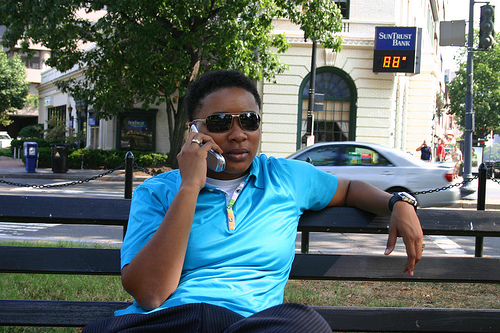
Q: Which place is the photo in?
A: It is at the road.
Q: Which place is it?
A: It is a road.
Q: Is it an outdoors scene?
A: Yes, it is outdoors.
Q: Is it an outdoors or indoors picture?
A: It is outdoors.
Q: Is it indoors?
A: No, it is outdoors.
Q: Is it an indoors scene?
A: No, it is outdoors.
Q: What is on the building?
A: The sign is on the building.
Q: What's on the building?
A: The sign is on the building.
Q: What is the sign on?
A: The sign is on the building.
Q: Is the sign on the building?
A: Yes, the sign is on the building.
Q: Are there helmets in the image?
A: No, there are no helmets.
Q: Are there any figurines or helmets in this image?
A: No, there are no helmets or figurines.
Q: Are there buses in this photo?
A: No, there are no buses.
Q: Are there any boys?
A: No, there are no boys.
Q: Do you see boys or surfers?
A: No, there are no boys or surfers.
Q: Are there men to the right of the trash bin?
A: Yes, there is a man to the right of the trash bin.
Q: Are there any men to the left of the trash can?
A: No, the man is to the right of the trash can.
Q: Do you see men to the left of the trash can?
A: No, the man is to the right of the trash can.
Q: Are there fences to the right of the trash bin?
A: No, there is a man to the right of the trash bin.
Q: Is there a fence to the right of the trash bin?
A: No, there is a man to the right of the trash bin.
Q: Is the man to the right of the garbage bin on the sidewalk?
A: Yes, the man is to the right of the trashcan.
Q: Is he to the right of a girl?
A: No, the man is to the right of the trashcan.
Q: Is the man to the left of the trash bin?
A: No, the man is to the right of the trash bin.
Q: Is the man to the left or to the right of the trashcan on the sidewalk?
A: The man is to the right of the trash bin.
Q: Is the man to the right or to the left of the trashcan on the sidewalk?
A: The man is to the right of the trash bin.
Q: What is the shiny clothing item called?
A: The clothing item is a polo shirt.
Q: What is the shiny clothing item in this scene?
A: The clothing item is a polo shirt.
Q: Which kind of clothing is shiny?
A: The clothing is a polo shirt.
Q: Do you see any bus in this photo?
A: No, there are no buses.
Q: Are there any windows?
A: Yes, there is a window.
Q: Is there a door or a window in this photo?
A: Yes, there is a window.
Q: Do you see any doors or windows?
A: Yes, there is a window.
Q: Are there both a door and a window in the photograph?
A: Yes, there are both a window and a door.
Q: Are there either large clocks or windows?
A: Yes, there is a large window.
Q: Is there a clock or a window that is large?
A: Yes, the window is large.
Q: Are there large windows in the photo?
A: Yes, there is a large window.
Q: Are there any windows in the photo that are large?
A: Yes, there is a window that is large.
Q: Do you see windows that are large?
A: Yes, there is a window that is large.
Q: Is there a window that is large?
A: Yes, there is a window that is large.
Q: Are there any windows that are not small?
A: Yes, there is a large window.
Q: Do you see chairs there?
A: No, there are no chairs.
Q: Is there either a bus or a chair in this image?
A: No, there are no chairs or buses.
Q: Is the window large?
A: Yes, the window is large.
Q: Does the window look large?
A: Yes, the window is large.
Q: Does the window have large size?
A: Yes, the window is large.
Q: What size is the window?
A: The window is large.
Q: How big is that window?
A: The window is large.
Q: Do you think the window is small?
A: No, the window is large.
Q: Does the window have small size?
A: No, the window is large.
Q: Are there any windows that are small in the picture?
A: No, there is a window but it is large.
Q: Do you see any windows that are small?
A: No, there is a window but it is large.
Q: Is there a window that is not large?
A: No, there is a window but it is large.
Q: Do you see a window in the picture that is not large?
A: No, there is a window but it is large.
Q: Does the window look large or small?
A: The window is large.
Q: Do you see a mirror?
A: No, there are no mirrors.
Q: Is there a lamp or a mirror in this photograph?
A: No, there are no mirrors or lamps.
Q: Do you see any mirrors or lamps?
A: No, there are no mirrors or lamps.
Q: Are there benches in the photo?
A: Yes, there is a bench.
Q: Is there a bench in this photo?
A: Yes, there is a bench.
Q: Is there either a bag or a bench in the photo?
A: Yes, there is a bench.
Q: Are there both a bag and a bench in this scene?
A: No, there is a bench but no bags.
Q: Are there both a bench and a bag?
A: No, there is a bench but no bags.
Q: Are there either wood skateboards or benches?
A: Yes, there is a wood bench.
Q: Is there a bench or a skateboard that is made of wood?
A: Yes, the bench is made of wood.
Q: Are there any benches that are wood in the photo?
A: Yes, there is a wood bench.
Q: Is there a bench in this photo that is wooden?
A: Yes, there is a bench that is wooden.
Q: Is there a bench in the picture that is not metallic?
A: Yes, there is a wooden bench.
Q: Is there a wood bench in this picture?
A: Yes, there is a bench that is made of wood.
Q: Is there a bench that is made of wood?
A: Yes, there is a bench that is made of wood.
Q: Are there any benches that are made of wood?
A: Yes, there is a bench that is made of wood.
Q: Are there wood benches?
A: Yes, there is a bench that is made of wood.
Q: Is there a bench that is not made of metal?
A: Yes, there is a bench that is made of wood.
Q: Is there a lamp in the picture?
A: No, there are no lamps.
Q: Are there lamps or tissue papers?
A: No, there are no lamps or tissue papers.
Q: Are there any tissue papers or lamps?
A: No, there are no lamps or tissue papers.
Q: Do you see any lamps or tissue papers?
A: No, there are no lamps or tissue papers.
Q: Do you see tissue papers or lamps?
A: No, there are no lamps or tissue papers.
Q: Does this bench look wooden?
A: Yes, the bench is wooden.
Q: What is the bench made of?
A: The bench is made of wood.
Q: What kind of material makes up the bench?
A: The bench is made of wood.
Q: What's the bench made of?
A: The bench is made of wood.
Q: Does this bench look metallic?
A: No, the bench is wooden.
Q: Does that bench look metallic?
A: No, the bench is wooden.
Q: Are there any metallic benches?
A: No, there is a bench but it is wooden.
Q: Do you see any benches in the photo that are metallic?
A: No, there is a bench but it is wooden.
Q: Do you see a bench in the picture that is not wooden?
A: No, there is a bench but it is wooden.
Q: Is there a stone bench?
A: No, there is a bench but it is made of wood.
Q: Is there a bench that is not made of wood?
A: No, there is a bench but it is made of wood.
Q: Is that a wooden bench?
A: Yes, that is a wooden bench.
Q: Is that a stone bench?
A: No, that is a wooden bench.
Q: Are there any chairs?
A: No, there are no chairs.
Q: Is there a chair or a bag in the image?
A: No, there are no chairs or bags.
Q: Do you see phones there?
A: Yes, there is a phone.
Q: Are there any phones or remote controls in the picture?
A: Yes, there is a phone.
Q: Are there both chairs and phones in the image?
A: No, there is a phone but no chairs.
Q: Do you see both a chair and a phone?
A: No, there is a phone but no chairs.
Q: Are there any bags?
A: No, there are no bags.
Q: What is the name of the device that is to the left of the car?
A: The device is a phone.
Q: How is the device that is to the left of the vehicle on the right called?
A: The device is a phone.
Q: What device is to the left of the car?
A: The device is a phone.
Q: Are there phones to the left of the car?
A: Yes, there is a phone to the left of the car.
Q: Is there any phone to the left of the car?
A: Yes, there is a phone to the left of the car.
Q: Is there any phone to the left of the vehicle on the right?
A: Yes, there is a phone to the left of the car.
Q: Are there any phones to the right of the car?
A: No, the phone is to the left of the car.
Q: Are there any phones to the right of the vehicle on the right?
A: No, the phone is to the left of the car.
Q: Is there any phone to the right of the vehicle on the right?
A: No, the phone is to the left of the car.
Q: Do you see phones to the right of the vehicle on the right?
A: No, the phone is to the left of the car.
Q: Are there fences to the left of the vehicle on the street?
A: No, there is a phone to the left of the car.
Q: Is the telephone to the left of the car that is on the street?
A: Yes, the telephone is to the left of the car.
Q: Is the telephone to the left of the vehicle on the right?
A: Yes, the telephone is to the left of the car.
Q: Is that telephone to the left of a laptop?
A: No, the telephone is to the left of the car.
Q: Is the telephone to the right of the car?
A: No, the telephone is to the left of the car.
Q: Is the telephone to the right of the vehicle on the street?
A: No, the telephone is to the left of the car.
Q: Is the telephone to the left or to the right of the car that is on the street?
A: The telephone is to the left of the car.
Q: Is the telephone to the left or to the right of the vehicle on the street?
A: The telephone is to the left of the car.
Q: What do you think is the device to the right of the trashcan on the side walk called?
A: The device is a phone.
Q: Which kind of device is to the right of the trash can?
A: The device is a phone.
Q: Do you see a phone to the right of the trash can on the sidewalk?
A: Yes, there is a phone to the right of the garbage can.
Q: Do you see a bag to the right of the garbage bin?
A: No, there is a phone to the right of the garbage bin.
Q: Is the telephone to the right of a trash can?
A: Yes, the telephone is to the right of a trash can.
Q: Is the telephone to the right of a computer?
A: No, the telephone is to the right of a trash can.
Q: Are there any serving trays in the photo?
A: No, there are no serving trays.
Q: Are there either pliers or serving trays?
A: No, there are no serving trays or pliers.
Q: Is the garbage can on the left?
A: Yes, the garbage can is on the left of the image.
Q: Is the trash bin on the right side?
A: No, the trash bin is on the left of the image.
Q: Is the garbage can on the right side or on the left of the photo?
A: The garbage can is on the left of the image.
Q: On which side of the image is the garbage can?
A: The garbage can is on the left of the image.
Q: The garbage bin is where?
A: The garbage bin is on the sidewalk.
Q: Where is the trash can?
A: The garbage bin is on the sidewalk.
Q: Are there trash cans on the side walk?
A: Yes, there is a trash can on the side walk.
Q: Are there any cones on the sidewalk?
A: No, there is a trash can on the sidewalk.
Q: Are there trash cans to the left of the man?
A: Yes, there is a trash can to the left of the man.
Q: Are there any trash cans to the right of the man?
A: No, the trash can is to the left of the man.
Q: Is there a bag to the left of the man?
A: No, there is a trash can to the left of the man.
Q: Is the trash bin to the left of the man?
A: Yes, the trash bin is to the left of the man.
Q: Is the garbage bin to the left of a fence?
A: No, the garbage bin is to the left of the man.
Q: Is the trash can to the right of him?
A: No, the trash can is to the left of a man.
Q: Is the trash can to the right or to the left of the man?
A: The trash can is to the left of the man.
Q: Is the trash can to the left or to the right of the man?
A: The trash can is to the left of the man.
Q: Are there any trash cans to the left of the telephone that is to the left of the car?
A: Yes, there is a trash can to the left of the phone.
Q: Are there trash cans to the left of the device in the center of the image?
A: Yes, there is a trash can to the left of the phone.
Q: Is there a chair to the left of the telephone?
A: No, there is a trash can to the left of the telephone.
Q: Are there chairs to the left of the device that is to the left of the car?
A: No, there is a trash can to the left of the telephone.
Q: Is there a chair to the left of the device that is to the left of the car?
A: No, there is a trash can to the left of the telephone.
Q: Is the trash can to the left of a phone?
A: Yes, the trash can is to the left of a phone.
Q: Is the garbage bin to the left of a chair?
A: No, the garbage bin is to the left of a phone.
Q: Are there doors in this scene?
A: Yes, there is a door.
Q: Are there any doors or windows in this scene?
A: Yes, there is a door.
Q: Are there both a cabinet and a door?
A: No, there is a door but no cabinets.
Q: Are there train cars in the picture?
A: No, there are no train cars.